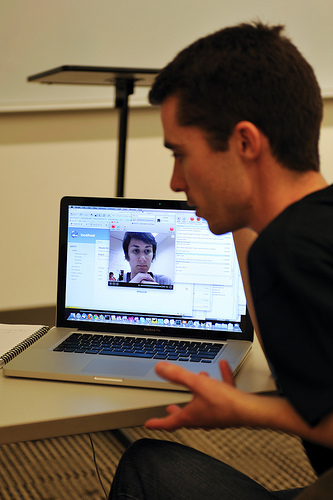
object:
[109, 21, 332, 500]
man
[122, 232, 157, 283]
person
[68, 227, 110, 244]
skype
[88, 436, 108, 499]
wire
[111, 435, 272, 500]
jeans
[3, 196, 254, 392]
laptop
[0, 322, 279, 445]
desk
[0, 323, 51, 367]
notebook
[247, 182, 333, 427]
shirt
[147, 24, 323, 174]
hair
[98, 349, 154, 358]
keys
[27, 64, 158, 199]
lamp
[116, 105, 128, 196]
pole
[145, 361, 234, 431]
hand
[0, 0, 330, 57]
ceiling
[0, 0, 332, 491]
room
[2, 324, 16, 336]
notes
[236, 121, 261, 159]
ear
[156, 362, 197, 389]
thumb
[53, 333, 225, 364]
keyboard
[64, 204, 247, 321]
screen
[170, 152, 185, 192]
nose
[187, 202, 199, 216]
mouth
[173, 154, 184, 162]
eye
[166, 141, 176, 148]
eyebrow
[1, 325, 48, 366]
binding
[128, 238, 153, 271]
face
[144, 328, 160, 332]
logo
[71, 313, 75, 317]
taskbar icons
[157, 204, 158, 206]
camera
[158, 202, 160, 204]
light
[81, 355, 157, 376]
touch pad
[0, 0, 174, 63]
wall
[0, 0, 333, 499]
house